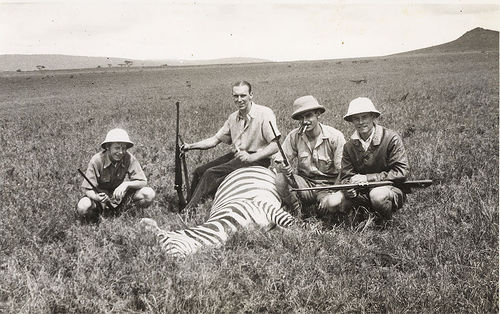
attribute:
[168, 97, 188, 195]
gun — standing up